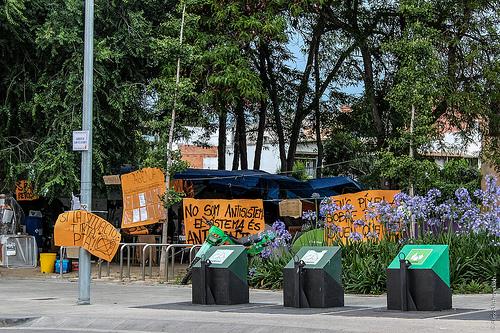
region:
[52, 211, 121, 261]
An orange sign on a pole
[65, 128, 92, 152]
A white sign on a pole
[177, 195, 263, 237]
An orange sign with black letters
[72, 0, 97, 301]
A tall metal pole near a street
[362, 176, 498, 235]
Purple flowers beside a road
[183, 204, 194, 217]
black letter on sign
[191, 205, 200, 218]
black letter on sign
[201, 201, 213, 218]
black letter on sign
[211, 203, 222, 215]
black letter on sign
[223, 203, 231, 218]
black letter on sign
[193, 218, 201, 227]
black letter on sign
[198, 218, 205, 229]
black letter on sign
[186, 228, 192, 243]
black letter on sign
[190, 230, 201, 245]
black letter on sign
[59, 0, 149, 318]
a pole on the sidewalk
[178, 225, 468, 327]
podiums on the sidewalk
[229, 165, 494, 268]
purple flowers to side walk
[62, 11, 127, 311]
the pole is grey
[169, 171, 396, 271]
black writing on signs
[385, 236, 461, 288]
green top of podium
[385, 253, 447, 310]
black bottom of podium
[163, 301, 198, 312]
shadow on the ground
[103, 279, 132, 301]
the sidewalk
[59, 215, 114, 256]
banner on the pole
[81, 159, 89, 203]
the pole is grey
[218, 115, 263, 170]
the tree trunks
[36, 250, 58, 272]
a yellow bucket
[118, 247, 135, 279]
the pole is grey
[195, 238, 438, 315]
the bins are green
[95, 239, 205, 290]
the bike rails are silver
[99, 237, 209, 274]
bike rails in the dirt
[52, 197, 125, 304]
sign on the pole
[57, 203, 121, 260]
the sign is orange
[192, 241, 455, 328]
bins on the sidewalk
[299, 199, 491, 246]
the flowers are purple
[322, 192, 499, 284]
flowers in the grass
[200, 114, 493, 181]
buildings behind the trees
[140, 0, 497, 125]
blue of daytime sky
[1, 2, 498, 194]
green leaves on tree branches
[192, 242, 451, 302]
three black and green boxes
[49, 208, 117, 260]
Orange sign on a metal pole.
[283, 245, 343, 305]
Green trash bin in between two others.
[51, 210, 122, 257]
sign is posted on pole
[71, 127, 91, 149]
sign is posted on pole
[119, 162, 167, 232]
sign is behind bike rack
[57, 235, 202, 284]
bike rack is beside sidewalk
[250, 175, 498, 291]
flowers are in front of trees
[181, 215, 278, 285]
motorbike is parked by flowers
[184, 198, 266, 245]
sign is behind bike rack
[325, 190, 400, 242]
sign is behind flowers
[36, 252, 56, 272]
bucket is on the ground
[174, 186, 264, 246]
a sign that is orange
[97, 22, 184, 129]
leaves that are green in color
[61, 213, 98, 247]
writing that is black in color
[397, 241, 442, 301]
a box that is black and green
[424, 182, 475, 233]
flowers that are blue in color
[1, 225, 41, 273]
a box that is grey in color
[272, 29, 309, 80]
a sky that is blue in color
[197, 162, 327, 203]
an umbrella that is blue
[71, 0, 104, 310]
long metal pole on sidewalk